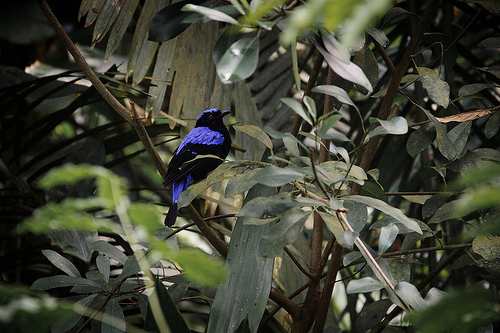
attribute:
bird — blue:
[155, 101, 245, 235]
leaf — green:
[42, 241, 78, 273]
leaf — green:
[95, 246, 116, 286]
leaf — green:
[90, 295, 130, 331]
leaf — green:
[213, 157, 298, 206]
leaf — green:
[335, 194, 422, 243]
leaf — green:
[370, 217, 404, 262]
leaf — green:
[348, 274, 384, 304]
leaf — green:
[370, 110, 411, 140]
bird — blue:
[161, 103, 228, 230]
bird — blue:
[166, 97, 233, 226]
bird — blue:
[162, 99, 229, 222]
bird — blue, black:
[162, 111, 238, 224]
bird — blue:
[166, 106, 236, 226]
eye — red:
[208, 108, 220, 125]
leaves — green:
[257, 6, 365, 166]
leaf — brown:
[436, 108, 484, 130]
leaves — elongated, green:
[101, 3, 216, 110]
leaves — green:
[31, 174, 227, 324]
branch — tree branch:
[36, 3, 157, 148]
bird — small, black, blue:
[149, 108, 237, 223]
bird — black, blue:
[161, 120, 238, 220]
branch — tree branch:
[44, 5, 163, 175]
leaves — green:
[244, 164, 396, 276]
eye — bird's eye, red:
[203, 107, 215, 127]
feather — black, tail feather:
[165, 207, 184, 225]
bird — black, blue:
[165, 109, 240, 228]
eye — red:
[208, 110, 215, 120]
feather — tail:
[162, 191, 182, 228]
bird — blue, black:
[162, 106, 239, 236]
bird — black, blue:
[167, 109, 229, 223]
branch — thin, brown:
[59, 27, 302, 319]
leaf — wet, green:
[213, 30, 270, 90]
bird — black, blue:
[152, 93, 240, 224]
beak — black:
[216, 102, 238, 123]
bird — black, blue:
[161, 104, 236, 231]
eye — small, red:
[207, 113, 216, 121]